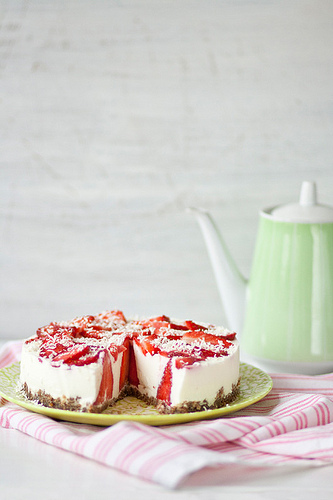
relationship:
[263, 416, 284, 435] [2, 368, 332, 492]
stripes on napkin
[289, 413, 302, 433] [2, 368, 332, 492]
stripes on napkin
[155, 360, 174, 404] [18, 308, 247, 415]
strawberry in pie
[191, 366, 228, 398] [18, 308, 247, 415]
surface of pie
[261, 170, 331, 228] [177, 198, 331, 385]
lid on jug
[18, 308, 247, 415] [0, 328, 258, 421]
pie on a plate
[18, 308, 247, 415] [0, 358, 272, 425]
pie on a plate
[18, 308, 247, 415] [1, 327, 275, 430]
pie on a plate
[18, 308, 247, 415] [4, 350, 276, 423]
pie on a plate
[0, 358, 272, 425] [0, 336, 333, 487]
plate on a napkin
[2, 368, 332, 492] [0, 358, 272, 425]
napkin on a plate